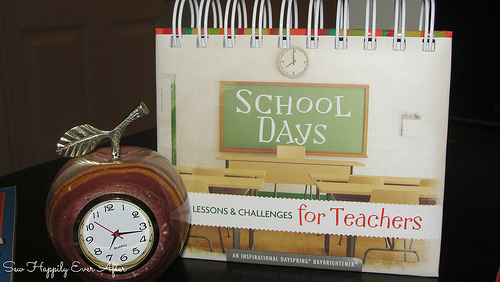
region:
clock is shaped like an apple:
[45, 101, 192, 279]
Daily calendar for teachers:
[155, 0, 452, 274]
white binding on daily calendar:
[168, 2, 439, 52]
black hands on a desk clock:
[108, 228, 143, 248]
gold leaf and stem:
[53, 100, 150, 162]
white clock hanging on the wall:
[276, 45, 308, 77]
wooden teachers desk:
[216, 144, 366, 176]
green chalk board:
[217, 78, 372, 156]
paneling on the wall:
[18, 20, 97, 123]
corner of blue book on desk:
[0, 185, 22, 280]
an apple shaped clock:
[41, 98, 194, 278]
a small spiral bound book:
[152, 0, 452, 277]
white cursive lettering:
[2, 256, 127, 278]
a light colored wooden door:
[0, 0, 175, 180]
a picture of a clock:
[275, 43, 311, 79]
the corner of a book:
[1, 183, 19, 280]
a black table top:
[0, 110, 499, 280]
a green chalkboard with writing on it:
[217, 78, 370, 157]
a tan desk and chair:
[213, 141, 364, 198]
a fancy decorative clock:
[42, 100, 192, 280]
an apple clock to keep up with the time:
[48, 95, 206, 278]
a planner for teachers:
[152, 33, 469, 275]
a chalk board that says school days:
[211, 73, 390, 164]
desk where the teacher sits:
[235, 138, 369, 182]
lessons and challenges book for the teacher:
[144, 31, 449, 269]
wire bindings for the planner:
[173, 5, 442, 55]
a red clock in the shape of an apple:
[46, 107, 228, 277]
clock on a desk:
[31, 105, 198, 279]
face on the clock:
[80, 207, 151, 261]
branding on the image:
[0, 253, 140, 278]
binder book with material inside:
[135, 0, 475, 272]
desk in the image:
[220, 150, 360, 187]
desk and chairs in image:
[320, 178, 447, 249]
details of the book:
[221, 247, 381, 272]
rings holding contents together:
[167, 3, 457, 47]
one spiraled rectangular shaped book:
[154, 0, 453, 273]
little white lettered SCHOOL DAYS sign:
[218, 77, 371, 159]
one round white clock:
[73, 190, 158, 273]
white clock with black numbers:
[78, 192, 160, 273]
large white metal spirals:
[163, 2, 447, 52]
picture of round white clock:
[277, 45, 308, 78]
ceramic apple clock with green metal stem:
[43, 95, 191, 277]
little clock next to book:
[36, 4, 453, 280]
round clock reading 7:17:
[73, 192, 158, 276]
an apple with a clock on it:
[40, 103, 192, 280]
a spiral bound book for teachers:
[150, 0, 455, 280]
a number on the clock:
[131, 208, 138, 223]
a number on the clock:
[136, 217, 146, 232]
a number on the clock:
[136, 236, 156, 243]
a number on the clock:
[126, 247, 141, 263]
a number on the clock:
[120, 249, 128, 265]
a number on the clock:
[107, 249, 114, 263]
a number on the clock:
[94, 246, 104, 258]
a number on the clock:
[78, 232, 93, 247]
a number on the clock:
[78, 215, 92, 229]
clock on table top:
[28, 103, 187, 274]